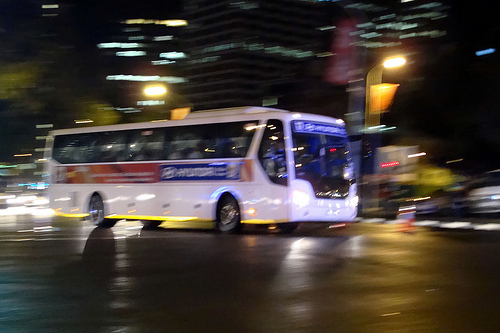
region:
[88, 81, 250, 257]
the bus is white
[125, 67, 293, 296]
the bus is white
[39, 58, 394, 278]
the bus is white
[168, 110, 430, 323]
the bus is white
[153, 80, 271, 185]
the bus is white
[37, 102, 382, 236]
white bus on the street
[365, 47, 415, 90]
street light on a pole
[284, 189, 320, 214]
front light on a bus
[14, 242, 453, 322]
black road where bus is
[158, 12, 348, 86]
buildings in the background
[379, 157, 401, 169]
red traffic light in the street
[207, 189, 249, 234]
front wheel of a bus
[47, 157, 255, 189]
advertisement along side of bus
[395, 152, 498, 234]
cars on a city street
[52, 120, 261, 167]
windows on side of a bus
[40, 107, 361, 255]
the bus is moving in traffic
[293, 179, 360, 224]
the headlights are lit the front of the bus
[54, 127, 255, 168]
passengers are seated on the bus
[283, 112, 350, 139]
the marquee is on the front of the bus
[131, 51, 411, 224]
street lamps are above the bus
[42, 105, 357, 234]
the bus is white with advertisements on the side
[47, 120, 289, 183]
glass windows are on the side of the bus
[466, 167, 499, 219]
a white vehicle is across from the bus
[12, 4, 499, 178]
tall buildings are behind the bus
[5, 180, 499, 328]
the street has traffic behind the bus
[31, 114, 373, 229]
white public bus speeding through the night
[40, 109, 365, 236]
public bus going quickly over the road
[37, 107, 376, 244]
white bus with lots of reflections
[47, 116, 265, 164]
tinted windows on a bus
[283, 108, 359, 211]
large windshield of a bus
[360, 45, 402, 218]
streetlight at night in a city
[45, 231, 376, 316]
shadow of a bus on the street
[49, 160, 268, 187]
bus side ad for hyundai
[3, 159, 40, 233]
city traffic and lights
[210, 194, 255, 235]
wheels on the bus